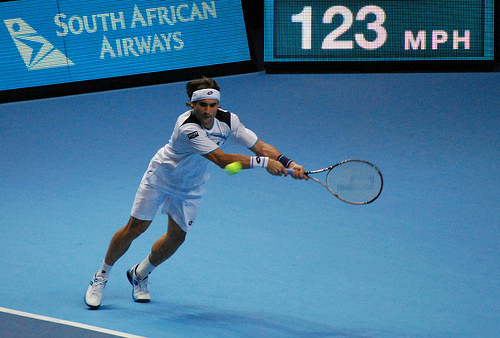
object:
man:
[80, 77, 309, 310]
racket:
[284, 159, 383, 206]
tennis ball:
[223, 161, 242, 174]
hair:
[184, 76, 220, 107]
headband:
[191, 88, 222, 101]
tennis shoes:
[125, 261, 151, 303]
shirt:
[140, 107, 259, 204]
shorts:
[129, 178, 206, 233]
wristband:
[248, 155, 270, 170]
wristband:
[273, 154, 293, 172]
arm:
[182, 128, 271, 172]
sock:
[137, 255, 156, 277]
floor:
[1, 71, 500, 337]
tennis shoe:
[82, 272, 107, 310]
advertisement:
[0, 0, 254, 92]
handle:
[284, 168, 294, 178]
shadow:
[98, 301, 364, 337]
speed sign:
[265, 1, 500, 70]